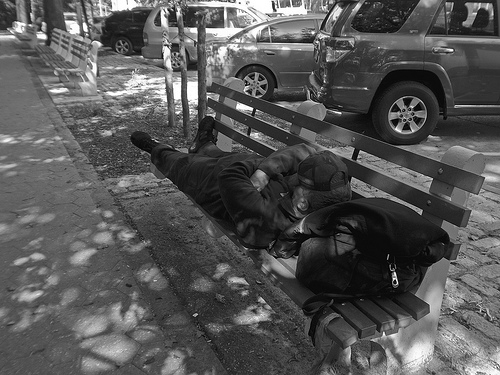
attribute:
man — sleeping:
[135, 113, 360, 248]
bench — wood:
[144, 73, 490, 373]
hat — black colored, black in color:
[286, 151, 352, 188]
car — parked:
[308, 4, 500, 145]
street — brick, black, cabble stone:
[126, 45, 500, 369]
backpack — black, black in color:
[294, 193, 455, 323]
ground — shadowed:
[15, 36, 499, 366]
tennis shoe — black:
[128, 129, 158, 157]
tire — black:
[368, 82, 443, 148]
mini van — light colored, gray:
[137, 2, 285, 77]